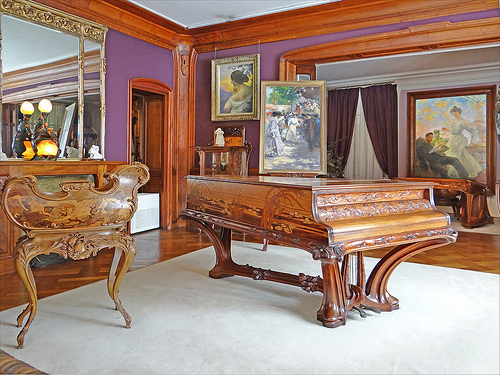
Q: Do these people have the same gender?
A: No, they are both male and female.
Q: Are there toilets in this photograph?
A: No, there are no toilets.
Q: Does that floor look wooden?
A: Yes, the floor is wooden.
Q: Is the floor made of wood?
A: Yes, the floor is made of wood.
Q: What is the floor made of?
A: The floor is made of wood.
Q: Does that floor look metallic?
A: No, the floor is wooden.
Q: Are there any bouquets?
A: No, there are no bouquets.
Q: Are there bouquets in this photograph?
A: No, there are no bouquets.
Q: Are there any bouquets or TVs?
A: No, there are no bouquets or tvs.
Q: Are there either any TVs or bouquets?
A: No, there are no bouquets or tvs.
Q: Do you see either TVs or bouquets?
A: No, there are no bouquets or tvs.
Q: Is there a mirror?
A: Yes, there is a mirror.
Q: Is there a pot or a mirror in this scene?
A: Yes, there is a mirror.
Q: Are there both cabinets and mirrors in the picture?
A: No, there is a mirror but no cabinets.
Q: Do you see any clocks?
A: No, there are no clocks.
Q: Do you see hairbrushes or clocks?
A: No, there are no clocks or hairbrushes.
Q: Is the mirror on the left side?
A: Yes, the mirror is on the left of the image.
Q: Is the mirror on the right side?
A: No, the mirror is on the left of the image.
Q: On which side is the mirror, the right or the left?
A: The mirror is on the left of the image.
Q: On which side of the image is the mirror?
A: The mirror is on the left of the image.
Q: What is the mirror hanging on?
A: The mirror is hanging on the wall.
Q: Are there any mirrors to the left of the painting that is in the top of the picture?
A: Yes, there is a mirror to the left of the painting.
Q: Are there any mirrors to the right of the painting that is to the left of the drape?
A: No, the mirror is to the left of the painting.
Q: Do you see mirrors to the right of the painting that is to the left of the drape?
A: No, the mirror is to the left of the painting.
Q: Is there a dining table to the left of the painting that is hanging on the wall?
A: No, there is a mirror to the left of the painting.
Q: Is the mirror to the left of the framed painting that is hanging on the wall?
A: Yes, the mirror is to the left of the painting.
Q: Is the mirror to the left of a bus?
A: No, the mirror is to the left of the painting.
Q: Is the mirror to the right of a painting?
A: No, the mirror is to the left of a painting.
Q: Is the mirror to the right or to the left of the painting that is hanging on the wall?
A: The mirror is to the left of the painting.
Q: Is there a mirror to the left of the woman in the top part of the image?
A: Yes, there is a mirror to the left of the woman.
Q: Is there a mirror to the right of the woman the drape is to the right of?
A: No, the mirror is to the left of the woman.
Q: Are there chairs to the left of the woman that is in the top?
A: No, there is a mirror to the left of the woman.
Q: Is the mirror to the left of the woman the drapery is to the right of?
A: Yes, the mirror is to the left of the woman.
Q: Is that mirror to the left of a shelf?
A: No, the mirror is to the left of the woman.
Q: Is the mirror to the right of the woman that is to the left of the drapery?
A: No, the mirror is to the left of the woman.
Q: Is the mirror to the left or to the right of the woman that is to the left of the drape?
A: The mirror is to the left of the woman.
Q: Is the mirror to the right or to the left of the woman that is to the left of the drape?
A: The mirror is to the left of the woman.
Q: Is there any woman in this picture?
A: Yes, there is a woman.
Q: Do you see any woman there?
A: Yes, there is a woman.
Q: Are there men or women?
A: Yes, there is a woman.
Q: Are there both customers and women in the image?
A: No, there is a woman but no customers.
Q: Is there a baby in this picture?
A: No, there are no babies.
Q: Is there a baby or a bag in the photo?
A: No, there are no babies or bags.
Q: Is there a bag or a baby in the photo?
A: No, there are no babies or bags.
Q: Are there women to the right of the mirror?
A: Yes, there is a woman to the right of the mirror.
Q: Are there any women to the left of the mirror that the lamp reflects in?
A: No, the woman is to the right of the mirror.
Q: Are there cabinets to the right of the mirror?
A: No, there is a woman to the right of the mirror.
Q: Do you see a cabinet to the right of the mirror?
A: No, there is a woman to the right of the mirror.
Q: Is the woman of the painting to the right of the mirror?
A: Yes, the woman is to the right of the mirror.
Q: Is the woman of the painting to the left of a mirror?
A: No, the woman is to the right of a mirror.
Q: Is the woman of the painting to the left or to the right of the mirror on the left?
A: The woman is to the right of the mirror.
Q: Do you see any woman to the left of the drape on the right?
A: Yes, there is a woman to the left of the drapery.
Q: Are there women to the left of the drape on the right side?
A: Yes, there is a woman to the left of the drapery.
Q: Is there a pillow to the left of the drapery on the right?
A: No, there is a woman to the left of the drape.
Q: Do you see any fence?
A: No, there are no fences.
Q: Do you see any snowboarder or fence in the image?
A: No, there are no fences or snowboarders.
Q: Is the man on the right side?
A: Yes, the man is on the right of the image.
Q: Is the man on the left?
A: No, the man is on the right of the image.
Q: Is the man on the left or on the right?
A: The man is on the right of the image.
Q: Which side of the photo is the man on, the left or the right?
A: The man is on the right of the image.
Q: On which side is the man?
A: The man is on the right of the image.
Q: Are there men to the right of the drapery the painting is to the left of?
A: Yes, there is a man to the right of the drapery.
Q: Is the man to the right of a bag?
A: No, the man is to the right of a drape.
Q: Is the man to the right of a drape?
A: Yes, the man is to the right of a drape.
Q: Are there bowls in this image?
A: No, there are no bowls.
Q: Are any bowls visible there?
A: No, there are no bowls.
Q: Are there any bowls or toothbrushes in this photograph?
A: No, there are no bowls or toothbrushes.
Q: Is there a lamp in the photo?
A: Yes, there is a lamp.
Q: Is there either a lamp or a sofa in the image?
A: Yes, there is a lamp.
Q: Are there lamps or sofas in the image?
A: Yes, there is a lamp.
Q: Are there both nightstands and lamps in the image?
A: No, there is a lamp but no nightstands.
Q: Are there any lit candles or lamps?
A: Yes, there is a lit lamp.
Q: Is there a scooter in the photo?
A: No, there are no scooters.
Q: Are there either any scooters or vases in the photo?
A: No, there are no scooters or vases.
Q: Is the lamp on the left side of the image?
A: Yes, the lamp is on the left of the image.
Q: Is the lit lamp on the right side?
A: No, the lamp is on the left of the image.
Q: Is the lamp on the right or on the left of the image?
A: The lamp is on the left of the image.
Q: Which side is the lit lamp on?
A: The lamp is on the left of the image.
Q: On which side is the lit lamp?
A: The lamp is on the left of the image.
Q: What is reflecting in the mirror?
A: The lamp is reflecting in the mirror.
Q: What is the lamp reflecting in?
A: The lamp is reflecting in the mirror.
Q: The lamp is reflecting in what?
A: The lamp is reflecting in the mirror.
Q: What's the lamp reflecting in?
A: The lamp is reflecting in the mirror.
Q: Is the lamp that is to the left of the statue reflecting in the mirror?
A: Yes, the lamp is reflecting in the mirror.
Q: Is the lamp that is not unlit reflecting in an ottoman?
A: No, the lamp is reflecting in the mirror.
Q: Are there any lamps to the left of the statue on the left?
A: Yes, there is a lamp to the left of the statue.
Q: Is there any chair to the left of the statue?
A: No, there is a lamp to the left of the statue.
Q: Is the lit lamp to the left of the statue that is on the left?
A: Yes, the lamp is to the left of the statue.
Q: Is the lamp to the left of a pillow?
A: No, the lamp is to the left of the statue.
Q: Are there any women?
A: Yes, there is a woman.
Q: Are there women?
A: Yes, there is a woman.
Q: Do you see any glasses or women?
A: Yes, there is a woman.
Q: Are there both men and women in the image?
A: Yes, there are both a woman and a man.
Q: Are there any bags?
A: No, there are no bags.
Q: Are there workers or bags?
A: No, there are no bags or workers.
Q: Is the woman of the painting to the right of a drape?
A: Yes, the woman is to the right of a drape.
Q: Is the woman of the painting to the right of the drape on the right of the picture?
A: Yes, the woman is to the right of the drapery.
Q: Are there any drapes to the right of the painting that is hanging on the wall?
A: Yes, there is a drape to the right of the painting.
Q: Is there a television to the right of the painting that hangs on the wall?
A: No, there is a drape to the right of the painting.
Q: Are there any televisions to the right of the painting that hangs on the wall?
A: No, there is a drape to the right of the painting.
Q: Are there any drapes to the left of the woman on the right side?
A: Yes, there is a drape to the left of the woman.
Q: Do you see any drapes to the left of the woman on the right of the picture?
A: Yes, there is a drape to the left of the woman.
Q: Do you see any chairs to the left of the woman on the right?
A: No, there is a drape to the left of the woman.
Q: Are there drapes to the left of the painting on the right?
A: Yes, there is a drape to the left of the painting.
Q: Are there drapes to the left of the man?
A: Yes, there is a drape to the left of the man.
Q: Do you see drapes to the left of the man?
A: Yes, there is a drape to the left of the man.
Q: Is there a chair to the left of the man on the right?
A: No, there is a drape to the left of the man.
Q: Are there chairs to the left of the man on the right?
A: No, there is a drape to the left of the man.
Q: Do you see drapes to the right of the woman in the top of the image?
A: Yes, there is a drape to the right of the woman.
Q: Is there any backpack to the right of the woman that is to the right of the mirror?
A: No, there is a drape to the right of the woman.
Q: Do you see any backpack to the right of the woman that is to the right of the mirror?
A: No, there is a drape to the right of the woman.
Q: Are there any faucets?
A: No, there are no faucets.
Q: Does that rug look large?
A: Yes, the rug is large.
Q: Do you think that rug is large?
A: Yes, the rug is large.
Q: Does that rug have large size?
A: Yes, the rug is large.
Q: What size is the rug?
A: The rug is large.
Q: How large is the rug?
A: The rug is large.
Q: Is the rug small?
A: No, the rug is large.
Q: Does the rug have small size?
A: No, the rug is large.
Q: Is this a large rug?
A: Yes, this is a large rug.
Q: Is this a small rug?
A: No, this is a large rug.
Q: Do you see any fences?
A: No, there are no fences.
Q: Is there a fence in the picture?
A: No, there are no fences.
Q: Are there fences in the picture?
A: No, there are no fences.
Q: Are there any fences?
A: No, there are no fences.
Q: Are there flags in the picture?
A: No, there are no flags.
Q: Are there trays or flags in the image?
A: No, there are no flags or trays.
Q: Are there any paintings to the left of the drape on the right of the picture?
A: Yes, there is a painting to the left of the drapery.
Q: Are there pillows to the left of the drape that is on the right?
A: No, there is a painting to the left of the drape.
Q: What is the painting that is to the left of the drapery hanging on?
A: The painting is hanging on the wall.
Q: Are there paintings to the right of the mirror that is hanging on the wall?
A: Yes, there is a painting to the right of the mirror.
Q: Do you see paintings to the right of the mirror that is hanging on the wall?
A: Yes, there is a painting to the right of the mirror.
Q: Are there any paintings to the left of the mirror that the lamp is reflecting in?
A: No, the painting is to the right of the mirror.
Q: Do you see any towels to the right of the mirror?
A: No, there is a painting to the right of the mirror.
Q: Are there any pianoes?
A: Yes, there is a piano.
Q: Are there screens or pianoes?
A: Yes, there is a piano.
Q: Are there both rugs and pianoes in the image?
A: Yes, there are both a piano and a rug.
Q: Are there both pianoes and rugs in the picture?
A: Yes, there are both a piano and a rug.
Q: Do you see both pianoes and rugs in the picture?
A: Yes, there are both a piano and a rug.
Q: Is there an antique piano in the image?
A: Yes, there is an antique piano.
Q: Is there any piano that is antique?
A: Yes, there is a piano that is antique.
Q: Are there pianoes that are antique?
A: Yes, there is a piano that is antique.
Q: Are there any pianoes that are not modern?
A: Yes, there is a antique piano.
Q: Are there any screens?
A: No, there are no screens.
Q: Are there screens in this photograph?
A: No, there are no screens.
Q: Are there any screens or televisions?
A: No, there are no screens or televisions.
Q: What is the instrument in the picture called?
A: The instrument is a piano.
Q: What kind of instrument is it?
A: The instrument is a piano.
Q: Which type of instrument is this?
A: This is a piano.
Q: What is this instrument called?
A: This is a piano.